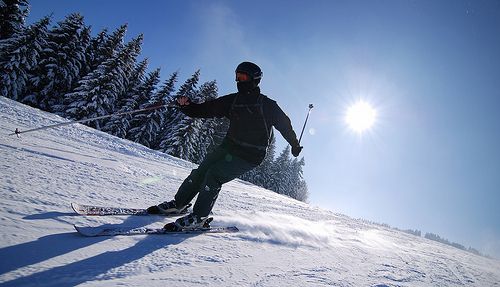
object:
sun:
[343, 100, 378, 133]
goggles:
[235, 72, 252, 83]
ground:
[418, 166, 455, 187]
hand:
[289, 144, 304, 156]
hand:
[175, 95, 193, 106]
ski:
[69, 199, 213, 216]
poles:
[286, 102, 315, 159]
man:
[147, 61, 303, 233]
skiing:
[14, 59, 313, 241]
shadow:
[0, 215, 210, 285]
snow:
[0, 92, 497, 284]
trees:
[248, 146, 308, 202]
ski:
[73, 222, 240, 237]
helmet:
[234, 61, 264, 87]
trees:
[0, 12, 227, 165]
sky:
[25, 2, 499, 253]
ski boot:
[148, 201, 190, 214]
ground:
[1, 97, 496, 285]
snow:
[2, 0, 203, 162]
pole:
[7, 102, 179, 140]